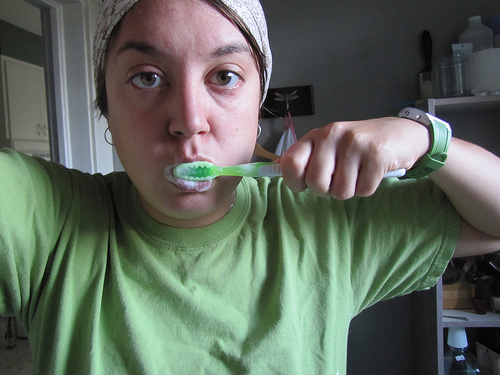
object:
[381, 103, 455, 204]
watch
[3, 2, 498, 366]
watch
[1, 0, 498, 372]
woman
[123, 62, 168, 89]
eye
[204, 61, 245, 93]
eye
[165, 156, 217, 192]
mouth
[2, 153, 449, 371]
shirt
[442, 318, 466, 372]
wash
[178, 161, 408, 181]
toothbrush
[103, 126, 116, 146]
earring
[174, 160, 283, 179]
teeth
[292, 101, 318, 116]
dark wood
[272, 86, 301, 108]
dragonfly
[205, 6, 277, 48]
bandana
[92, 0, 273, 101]
hat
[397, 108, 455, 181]
wrist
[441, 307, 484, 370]
shelf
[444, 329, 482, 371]
mouthwash